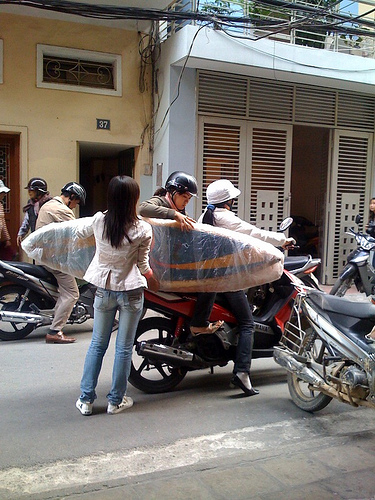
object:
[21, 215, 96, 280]
plastic bag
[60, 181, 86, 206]
helmet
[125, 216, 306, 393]
gmotorcycle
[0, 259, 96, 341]
gmotorcycle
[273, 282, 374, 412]
gmotorcycle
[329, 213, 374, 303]
gmotorcycle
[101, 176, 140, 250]
hair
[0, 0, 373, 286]
building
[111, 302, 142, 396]
leg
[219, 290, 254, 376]
leg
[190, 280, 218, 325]
leg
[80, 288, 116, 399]
leg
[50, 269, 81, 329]
leg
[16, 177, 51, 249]
person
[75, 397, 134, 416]
shoes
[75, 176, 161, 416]
girl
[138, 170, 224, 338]
girl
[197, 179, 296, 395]
girl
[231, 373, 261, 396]
shoe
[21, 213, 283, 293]
big board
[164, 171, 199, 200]
helmet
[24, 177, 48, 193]
helmet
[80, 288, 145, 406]
jeans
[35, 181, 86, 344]
guy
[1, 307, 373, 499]
street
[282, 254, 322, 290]
motorcycle